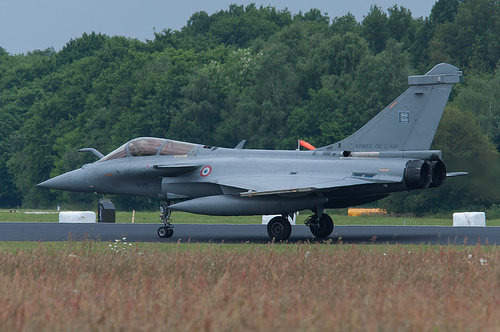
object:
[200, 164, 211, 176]
logo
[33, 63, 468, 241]
aircraft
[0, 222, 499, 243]
runway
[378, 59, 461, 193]
tail end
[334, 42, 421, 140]
trees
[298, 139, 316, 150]
windsock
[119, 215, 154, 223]
grass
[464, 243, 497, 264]
grass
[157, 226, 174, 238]
small wheel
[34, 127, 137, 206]
front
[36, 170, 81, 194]
nose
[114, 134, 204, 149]
top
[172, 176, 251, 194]
front of wing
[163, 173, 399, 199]
wing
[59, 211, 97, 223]
white blocks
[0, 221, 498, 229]
edge of path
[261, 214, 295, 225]
white blocks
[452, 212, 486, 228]
white blocks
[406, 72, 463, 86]
bar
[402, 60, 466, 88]
top of tail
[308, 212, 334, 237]
wheels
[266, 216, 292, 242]
wheels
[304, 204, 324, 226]
landing gear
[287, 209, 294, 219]
landing gear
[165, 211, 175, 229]
landing gear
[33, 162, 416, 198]
side of jet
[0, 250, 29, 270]
grass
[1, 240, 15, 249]
grass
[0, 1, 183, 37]
sky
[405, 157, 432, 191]
exhaust pipes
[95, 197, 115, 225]
garbage can